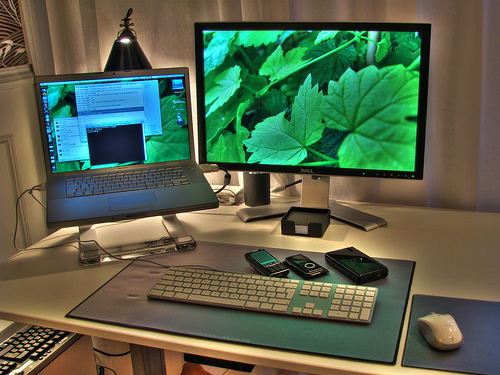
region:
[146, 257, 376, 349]
keyboard to a computer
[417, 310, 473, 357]
mouse to a computer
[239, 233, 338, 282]
phones on a desk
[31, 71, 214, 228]
laptop on a desk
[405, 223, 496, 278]
desk where monitors are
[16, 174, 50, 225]
wire to a laptop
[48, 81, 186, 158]
screen of a laptop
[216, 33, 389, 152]
leaves on a computer screen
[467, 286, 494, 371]
mouse pad on a desk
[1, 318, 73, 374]
keyboard to a laptop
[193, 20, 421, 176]
the monitor is turned on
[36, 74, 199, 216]
the laptop is turned on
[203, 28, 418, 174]
the screen is showing leaves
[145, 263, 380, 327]
a keyboard is on the desk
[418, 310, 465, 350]
a mouse is on the desk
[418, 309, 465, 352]
the mouse is white in color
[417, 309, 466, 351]
the mouse is made of plastic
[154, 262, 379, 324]
the keys are made of plastic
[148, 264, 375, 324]
the keys are white in color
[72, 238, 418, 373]
a mat is underneath the keyboard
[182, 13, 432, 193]
larger monitor behind keyboard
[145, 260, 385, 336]
keyboard in front of monitor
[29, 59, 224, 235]
laptop to the left of the monitor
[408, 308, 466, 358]
white mouse to the right of keyboard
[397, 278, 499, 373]
blue mouse pad under mouse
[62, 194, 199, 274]
laptop on raised platform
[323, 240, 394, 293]
nintendo game system behind keyboard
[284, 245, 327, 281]
small cell phone behind keyboard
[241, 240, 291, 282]
cell phone to the left of cell phone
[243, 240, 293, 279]
cell phone screen is green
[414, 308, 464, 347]
a white computer mouse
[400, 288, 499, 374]
a black mouse pad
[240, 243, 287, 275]
a small black cellphone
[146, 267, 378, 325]
a large white computer keyboard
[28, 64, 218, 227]
a gray laptop computer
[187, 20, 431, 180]
a desktop computer monitor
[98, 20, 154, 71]
part of a desk lamp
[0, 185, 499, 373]
part of a white desk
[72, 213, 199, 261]
a gray computer stand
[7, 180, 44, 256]
a white computer cord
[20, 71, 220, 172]
Screen of a laptop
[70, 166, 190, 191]
Keyboard on the laptop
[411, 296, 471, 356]
A mouse in the photo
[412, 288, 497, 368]
A mouse pad on the table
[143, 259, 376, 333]
A keyboard on the table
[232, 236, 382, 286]
Mobile phones on the table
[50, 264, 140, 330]
A table in the photo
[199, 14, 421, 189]
A monitor screen in the photo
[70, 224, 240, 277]
Stand of a computer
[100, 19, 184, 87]
Light at the back